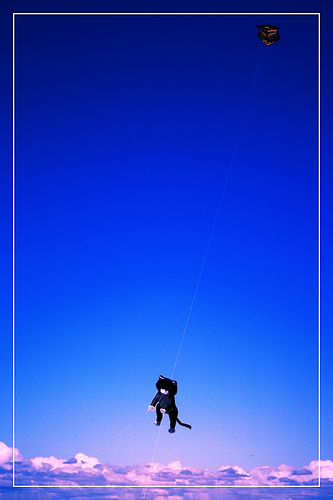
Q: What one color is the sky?
A: Blue.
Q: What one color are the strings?
A: White.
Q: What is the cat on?
A: A string.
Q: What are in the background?
A: Clouds.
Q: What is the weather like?
A: Partly cloudy.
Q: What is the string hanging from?
A: Parachute.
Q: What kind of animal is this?
A: Cat.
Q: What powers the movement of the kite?
A: Wind.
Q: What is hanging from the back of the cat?
A: Tail.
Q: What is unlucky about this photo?
A: Black cat.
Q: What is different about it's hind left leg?
A: There is no white.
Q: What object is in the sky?
A: A kite.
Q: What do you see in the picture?
A: Cat.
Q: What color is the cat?
A: Black and white.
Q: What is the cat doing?
A: Flying.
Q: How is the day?
A: Sunny.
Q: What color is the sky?
A: Blue.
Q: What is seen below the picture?
A: Clouds.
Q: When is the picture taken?
A: Daytime.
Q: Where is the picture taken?
A: In the sky.